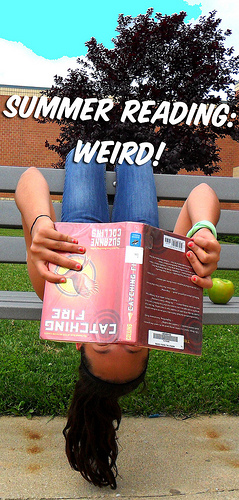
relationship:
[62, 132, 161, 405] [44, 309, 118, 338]
girl reads book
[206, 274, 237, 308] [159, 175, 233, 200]
apple on bench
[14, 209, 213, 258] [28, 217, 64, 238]
bracelet on wrist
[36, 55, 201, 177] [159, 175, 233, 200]
tree behind bench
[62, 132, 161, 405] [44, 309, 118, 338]
girl reading book